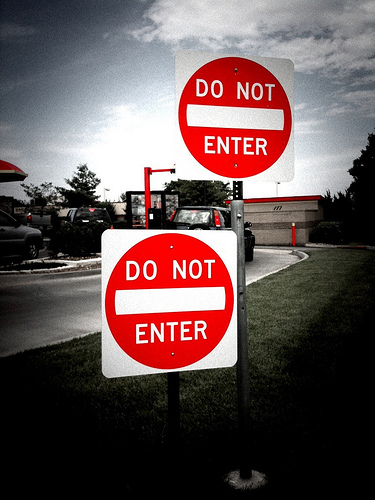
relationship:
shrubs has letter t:
[308, 188, 374, 244] [264, 83, 276, 100]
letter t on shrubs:
[264, 83, 276, 100] [308, 188, 374, 244]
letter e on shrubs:
[201, 134, 215, 156] [308, 188, 374, 244]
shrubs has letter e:
[308, 188, 374, 244] [201, 134, 215, 156]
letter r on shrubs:
[255, 137, 266, 156] [308, 188, 374, 244]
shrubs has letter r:
[308, 188, 374, 244] [255, 137, 266, 156]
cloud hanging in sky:
[118, 0, 363, 81] [1, 2, 363, 203]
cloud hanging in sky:
[122, 0, 374, 88] [1, 2, 363, 203]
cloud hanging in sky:
[293, 100, 309, 110] [1, 2, 363, 203]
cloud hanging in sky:
[101, 29, 111, 39] [1, 2, 363, 203]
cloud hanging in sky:
[0, 22, 36, 38] [1, 2, 363, 203]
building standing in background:
[241, 194, 325, 246] [1, 125, 361, 280]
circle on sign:
[104, 232, 234, 369] [98, 228, 239, 373]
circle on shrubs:
[179, 56, 290, 179] [308, 188, 374, 244]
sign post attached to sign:
[164, 336, 181, 498] [104, 213, 246, 375]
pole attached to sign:
[229, 174, 251, 479] [177, 35, 294, 189]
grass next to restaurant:
[276, 254, 368, 356] [2, 119, 52, 215]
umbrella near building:
[0, 164, 28, 187] [241, 194, 325, 246]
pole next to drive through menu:
[143, 166, 152, 228] [128, 189, 177, 219]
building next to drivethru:
[246, 187, 325, 247] [191, 203, 272, 262]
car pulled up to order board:
[155, 199, 258, 252] [127, 188, 192, 235]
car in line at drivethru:
[42, 210, 108, 258] [1, 187, 163, 229]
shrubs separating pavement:
[308, 202, 373, 244] [0, 268, 101, 359]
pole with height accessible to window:
[145, 157, 157, 228] [167, 200, 209, 223]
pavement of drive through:
[7, 285, 79, 346] [0, 208, 45, 266]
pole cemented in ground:
[226, 391, 262, 490] [287, 351, 353, 486]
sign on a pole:
[188, 50, 303, 193] [226, 183, 245, 480]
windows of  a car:
[182, 203, 229, 228] [57, 198, 99, 242]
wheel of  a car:
[36, 243, 44, 253] [8, 218, 42, 273]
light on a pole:
[162, 170, 175, 176] [134, 166, 171, 340]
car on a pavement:
[42, 205, 113, 257] [0, 268, 101, 359]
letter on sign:
[189, 76, 208, 100] [160, 75, 303, 167]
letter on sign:
[123, 259, 139, 287] [104, 213, 246, 375]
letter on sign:
[141, 260, 157, 281] [98, 228, 239, 373]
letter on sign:
[173, 258, 185, 279] [106, 228, 232, 386]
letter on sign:
[188, 260, 202, 283] [98, 228, 239, 373]